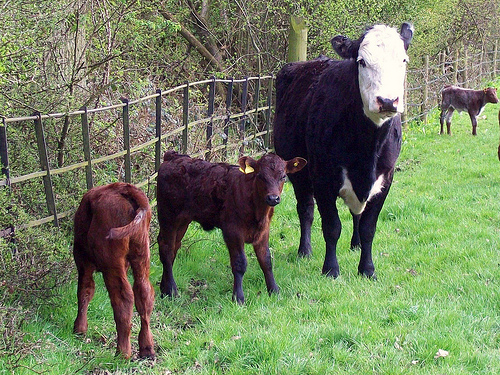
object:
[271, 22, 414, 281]
cow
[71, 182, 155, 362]
cow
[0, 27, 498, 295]
fence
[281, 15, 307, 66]
fence post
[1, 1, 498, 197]
trees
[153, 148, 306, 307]
calf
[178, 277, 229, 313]
grass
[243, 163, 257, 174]
tag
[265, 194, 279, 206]
nose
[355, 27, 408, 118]
face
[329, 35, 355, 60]
ear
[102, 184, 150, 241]
tail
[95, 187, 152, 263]
rear end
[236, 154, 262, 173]
right ear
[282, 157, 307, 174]
left ear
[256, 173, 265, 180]
right eye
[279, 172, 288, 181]
left eye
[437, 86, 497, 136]
calf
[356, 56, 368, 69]
right eye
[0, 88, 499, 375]
field